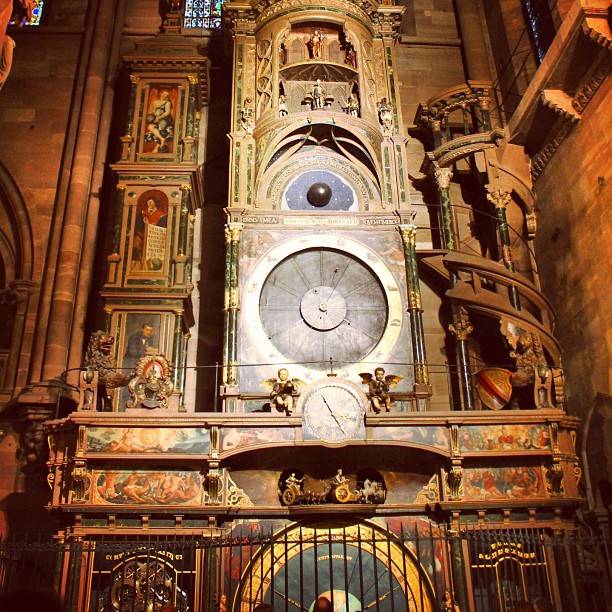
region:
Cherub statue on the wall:
[354, 357, 407, 414]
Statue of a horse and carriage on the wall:
[278, 465, 384, 513]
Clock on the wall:
[300, 381, 368, 447]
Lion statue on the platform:
[73, 319, 140, 408]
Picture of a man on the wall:
[118, 310, 164, 377]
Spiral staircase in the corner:
[395, 72, 569, 412]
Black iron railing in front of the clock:
[2, 524, 606, 609]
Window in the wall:
[181, 0, 220, 32]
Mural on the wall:
[91, 463, 209, 513]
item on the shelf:
[264, 378, 298, 410]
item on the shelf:
[515, 370, 563, 407]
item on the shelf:
[374, 378, 396, 405]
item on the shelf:
[355, 476, 396, 509]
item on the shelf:
[324, 467, 351, 500]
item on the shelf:
[142, 217, 164, 254]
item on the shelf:
[118, 84, 174, 160]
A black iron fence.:
[6, 518, 610, 610]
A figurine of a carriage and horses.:
[277, 469, 390, 506]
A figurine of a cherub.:
[356, 365, 405, 413]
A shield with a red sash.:
[471, 364, 512, 410]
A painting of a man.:
[130, 189, 174, 279]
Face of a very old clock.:
[237, 221, 408, 387]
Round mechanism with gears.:
[109, 557, 179, 610]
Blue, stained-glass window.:
[182, 2, 223, 30]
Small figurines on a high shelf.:
[275, 20, 365, 119]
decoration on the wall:
[279, 462, 310, 504]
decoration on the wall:
[329, 467, 340, 506]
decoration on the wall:
[369, 374, 388, 404]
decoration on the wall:
[267, 372, 308, 417]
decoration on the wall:
[514, 364, 528, 400]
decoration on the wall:
[138, 374, 169, 407]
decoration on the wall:
[87, 320, 120, 364]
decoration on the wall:
[445, 181, 497, 226]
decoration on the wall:
[147, 197, 215, 251]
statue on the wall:
[265, 366, 299, 411]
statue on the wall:
[367, 359, 401, 412]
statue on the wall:
[83, 331, 139, 404]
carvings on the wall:
[281, 470, 387, 504]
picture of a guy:
[126, 317, 156, 352]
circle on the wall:
[243, 233, 399, 376]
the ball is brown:
[306, 182, 334, 208]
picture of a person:
[132, 190, 166, 225]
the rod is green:
[440, 190, 455, 244]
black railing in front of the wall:
[16, 517, 595, 611]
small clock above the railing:
[290, 380, 375, 441]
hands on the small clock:
[312, 392, 348, 436]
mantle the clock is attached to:
[58, 400, 572, 466]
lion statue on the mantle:
[60, 320, 141, 417]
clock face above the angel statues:
[237, 234, 400, 368]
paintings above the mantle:
[113, 59, 192, 397]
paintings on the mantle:
[63, 422, 557, 507]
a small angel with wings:
[359, 366, 401, 412]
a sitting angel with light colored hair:
[264, 365, 305, 416]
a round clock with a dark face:
[239, 235, 403, 386]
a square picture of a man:
[122, 313, 163, 361]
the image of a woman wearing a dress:
[141, 81, 182, 159]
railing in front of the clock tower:
[0, 520, 609, 610]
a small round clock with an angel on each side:
[266, 367, 404, 444]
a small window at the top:
[181, 0, 222, 28]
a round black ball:
[307, 182, 333, 208]